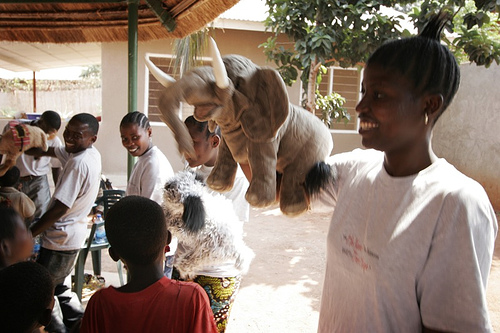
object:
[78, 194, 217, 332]
child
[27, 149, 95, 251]
bad image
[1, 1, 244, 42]
grass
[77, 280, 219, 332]
shirt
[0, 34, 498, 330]
people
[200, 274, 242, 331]
lesso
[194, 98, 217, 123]
mouth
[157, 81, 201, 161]
trunk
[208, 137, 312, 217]
legs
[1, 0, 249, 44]
awning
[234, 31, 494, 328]
person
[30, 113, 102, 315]
male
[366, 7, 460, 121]
black hair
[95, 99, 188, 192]
woman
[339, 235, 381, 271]
words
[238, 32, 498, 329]
woman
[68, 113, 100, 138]
hair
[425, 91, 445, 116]
ear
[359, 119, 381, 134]
teeth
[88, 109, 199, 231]
person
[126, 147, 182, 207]
gray shirt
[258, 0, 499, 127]
tree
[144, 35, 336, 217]
elephant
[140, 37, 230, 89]
tusks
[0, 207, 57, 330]
child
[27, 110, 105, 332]
person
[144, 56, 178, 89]
horns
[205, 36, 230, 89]
horns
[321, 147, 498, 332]
shirt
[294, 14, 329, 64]
leaves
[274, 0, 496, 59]
tree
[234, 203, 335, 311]
shadow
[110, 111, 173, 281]
people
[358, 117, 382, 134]
mouth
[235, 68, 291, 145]
ear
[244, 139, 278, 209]
leg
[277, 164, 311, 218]
leg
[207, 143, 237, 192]
leg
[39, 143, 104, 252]
shirt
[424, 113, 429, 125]
earring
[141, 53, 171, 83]
tusk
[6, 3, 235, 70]
umbrella